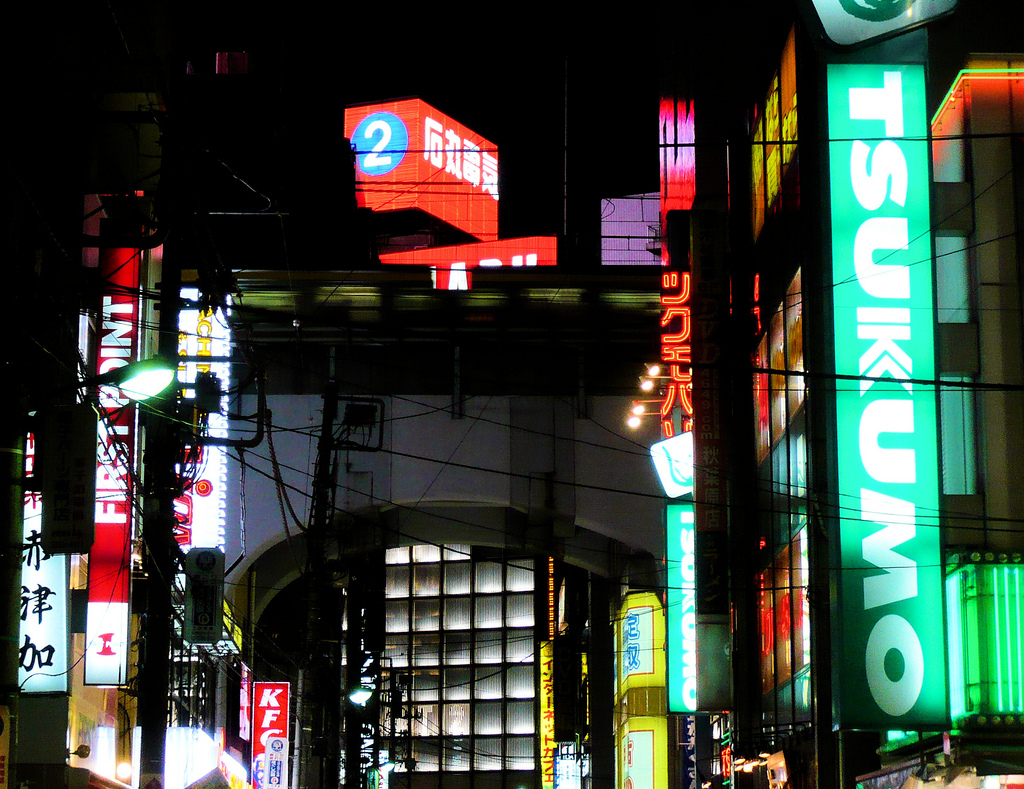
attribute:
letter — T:
[831, 54, 927, 138]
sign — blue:
[825, 62, 955, 731]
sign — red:
[257, 679, 293, 787]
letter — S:
[845, 132, 910, 210]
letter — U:
[854, 394, 919, 485]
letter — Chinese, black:
[20, 526, 55, 570]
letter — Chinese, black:
[29, 573, 53, 623]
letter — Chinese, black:
[16, 582, 30, 619]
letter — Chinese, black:
[18, 634, 57, 673]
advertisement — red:
[340, 96, 503, 243]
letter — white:
[418, 113, 442, 168]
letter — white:
[443, 128, 459, 174]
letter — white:
[459, 134, 481, 184]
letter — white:
[482, 148, 502, 196]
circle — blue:
[365, 53, 450, 239]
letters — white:
[806, 83, 979, 775]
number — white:
[791, 81, 960, 712]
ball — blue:
[312, 105, 429, 203]